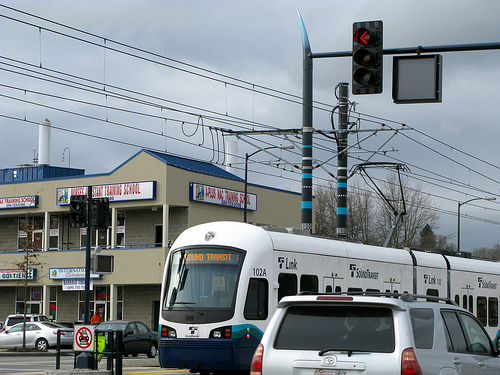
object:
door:
[276, 271, 317, 305]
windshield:
[162, 244, 245, 325]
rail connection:
[356, 162, 409, 247]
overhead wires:
[0, 4, 499, 224]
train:
[159, 220, 500, 370]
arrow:
[353, 31, 372, 44]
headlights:
[159, 324, 232, 340]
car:
[249, 295, 500, 375]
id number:
[253, 268, 267, 276]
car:
[95, 321, 159, 358]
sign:
[189, 182, 258, 211]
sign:
[47, 178, 157, 206]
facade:
[4, 150, 166, 333]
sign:
[73, 325, 103, 359]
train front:
[157, 219, 275, 370]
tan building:
[8, 152, 151, 278]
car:
[0, 320, 74, 351]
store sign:
[186, 182, 257, 212]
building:
[0, 148, 315, 353]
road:
[27, 347, 167, 371]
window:
[278, 272, 319, 301]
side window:
[243, 277, 269, 320]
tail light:
[249, 343, 264, 374]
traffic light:
[350, 21, 383, 94]